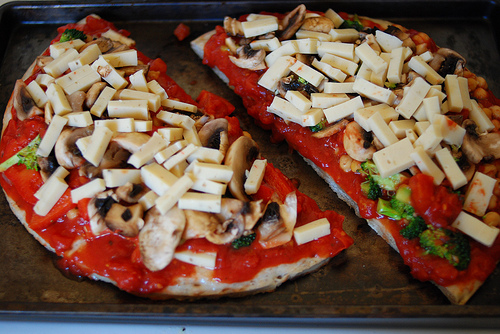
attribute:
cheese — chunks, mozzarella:
[296, 220, 334, 242]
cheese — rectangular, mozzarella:
[177, 191, 224, 213]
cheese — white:
[31, 111, 70, 159]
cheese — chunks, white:
[86, 127, 113, 162]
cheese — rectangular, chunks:
[107, 97, 152, 119]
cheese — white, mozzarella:
[464, 165, 496, 217]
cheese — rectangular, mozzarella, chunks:
[370, 134, 416, 179]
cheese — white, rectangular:
[322, 94, 365, 122]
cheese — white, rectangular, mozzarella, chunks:
[357, 39, 390, 81]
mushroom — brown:
[98, 200, 141, 236]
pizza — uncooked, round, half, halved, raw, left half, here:
[0, 12, 351, 302]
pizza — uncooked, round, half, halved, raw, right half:
[190, 7, 500, 308]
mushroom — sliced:
[462, 118, 499, 162]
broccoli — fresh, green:
[57, 26, 84, 46]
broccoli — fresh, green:
[21, 141, 42, 171]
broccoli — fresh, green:
[232, 232, 257, 252]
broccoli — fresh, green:
[419, 224, 474, 272]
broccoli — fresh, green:
[404, 212, 426, 240]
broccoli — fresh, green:
[360, 157, 405, 197]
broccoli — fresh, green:
[291, 74, 306, 95]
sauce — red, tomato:
[0, 121, 337, 295]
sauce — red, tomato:
[205, 35, 456, 278]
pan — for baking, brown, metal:
[3, 3, 500, 317]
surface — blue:
[1, 321, 500, 334]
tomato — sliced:
[29, 187, 73, 229]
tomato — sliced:
[410, 173, 459, 226]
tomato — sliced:
[6, 159, 43, 204]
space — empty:
[104, 43, 403, 243]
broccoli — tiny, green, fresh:
[223, 46, 233, 53]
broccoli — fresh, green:
[339, 11, 365, 32]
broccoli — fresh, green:
[311, 118, 325, 135]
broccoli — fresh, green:
[375, 180, 419, 228]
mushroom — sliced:
[224, 130, 260, 203]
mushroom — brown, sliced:
[12, 76, 43, 119]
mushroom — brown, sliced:
[434, 47, 466, 79]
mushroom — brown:
[342, 125, 377, 158]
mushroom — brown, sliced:
[279, 0, 306, 36]